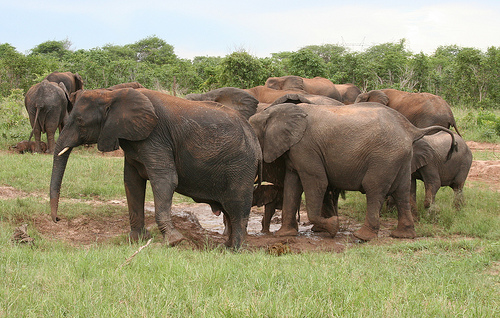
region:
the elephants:
[87, 76, 475, 251]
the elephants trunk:
[48, 161, 64, 218]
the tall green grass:
[197, 264, 272, 316]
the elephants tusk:
[56, 146, 71, 157]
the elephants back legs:
[361, 178, 416, 235]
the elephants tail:
[419, 128, 461, 153]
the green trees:
[95, 43, 172, 79]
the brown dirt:
[54, 223, 109, 240]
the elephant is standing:
[75, 88, 261, 245]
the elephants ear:
[266, 114, 304, 166]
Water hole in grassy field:
[120, 198, 352, 241]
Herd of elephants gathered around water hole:
[47, 75, 476, 243]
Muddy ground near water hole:
[165, 208, 364, 253]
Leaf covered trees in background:
[4, 37, 496, 110]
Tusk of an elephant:
[50, 141, 73, 159]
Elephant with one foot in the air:
[248, 98, 460, 247]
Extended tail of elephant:
[414, 119, 458, 166]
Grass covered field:
[7, 244, 497, 314]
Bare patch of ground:
[32, 213, 182, 248]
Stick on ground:
[115, 237, 157, 267]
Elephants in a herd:
[25, 70, 471, 245]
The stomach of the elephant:
[181, 178, 211, 203]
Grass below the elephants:
[5, 152, 498, 317]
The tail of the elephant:
[256, 150, 263, 185]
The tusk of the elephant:
[58, 145, 69, 155]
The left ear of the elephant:
[103, 92, 161, 149]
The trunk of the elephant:
[51, 141, 71, 221]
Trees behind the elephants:
[3, 44, 498, 104]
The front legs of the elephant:
[124, 169, 186, 244]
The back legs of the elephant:
[220, 196, 249, 248]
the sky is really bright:
[6, 3, 496, 49]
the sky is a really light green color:
[0, 0, 488, 43]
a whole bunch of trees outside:
[6, 39, 494, 101]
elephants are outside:
[24, 70, 467, 250]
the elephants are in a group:
[28, 70, 467, 242]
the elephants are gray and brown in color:
[20, 60, 467, 249]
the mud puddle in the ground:
[156, 189, 407, 252]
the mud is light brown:
[157, 185, 382, 256]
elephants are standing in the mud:
[80, 90, 425, 238]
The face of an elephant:
[52, 90, 158, 221]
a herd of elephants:
[28, 68, 473, 240]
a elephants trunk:
[43, 156, 77, 228]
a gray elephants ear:
[95, 89, 163, 151]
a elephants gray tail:
[414, 123, 463, 168]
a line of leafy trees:
[1, 45, 497, 85]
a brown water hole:
[170, 182, 287, 250]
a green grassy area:
[0, 250, 459, 315]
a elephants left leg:
[300, 186, 347, 241]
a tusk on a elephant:
[53, 138, 72, 155]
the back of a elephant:
[20, 79, 64, 149]